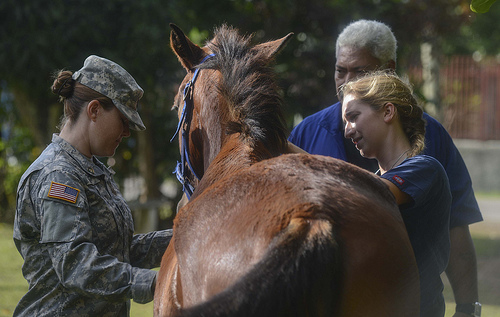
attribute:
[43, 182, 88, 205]
flag — american, usa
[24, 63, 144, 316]
woman — veteran, blonde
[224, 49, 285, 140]
mane — black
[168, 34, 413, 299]
horse — brown, young, reddishbrown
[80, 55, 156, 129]
hat — military, tan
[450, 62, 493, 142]
fence — metal, wooden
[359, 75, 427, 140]
hair — blonde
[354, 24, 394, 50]
hair — white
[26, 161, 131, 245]
uniform — camo, military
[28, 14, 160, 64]
trees — green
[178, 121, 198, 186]
halter — blue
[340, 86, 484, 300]
women — young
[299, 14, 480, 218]
man — older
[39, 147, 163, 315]
jacket — military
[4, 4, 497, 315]
photo — outdoor